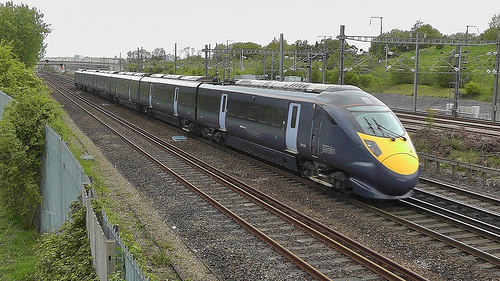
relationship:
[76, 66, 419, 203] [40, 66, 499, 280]
train on tracks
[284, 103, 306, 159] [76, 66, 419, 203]
door on train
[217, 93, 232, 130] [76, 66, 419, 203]
door on train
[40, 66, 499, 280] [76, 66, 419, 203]
tracks for trains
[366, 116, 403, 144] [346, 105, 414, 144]
wipers on windshield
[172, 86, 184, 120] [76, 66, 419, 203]
door on train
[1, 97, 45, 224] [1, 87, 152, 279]
shrub on fence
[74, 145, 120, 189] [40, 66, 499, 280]
grass by tracks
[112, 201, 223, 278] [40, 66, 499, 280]
gravel by tracks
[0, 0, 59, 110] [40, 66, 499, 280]
trees by tracks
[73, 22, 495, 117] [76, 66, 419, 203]
power lines by train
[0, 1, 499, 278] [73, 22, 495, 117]
picture has power lines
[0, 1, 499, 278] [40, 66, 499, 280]
picture has tracks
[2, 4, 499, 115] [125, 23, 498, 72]
background has trees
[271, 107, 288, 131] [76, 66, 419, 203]
window on train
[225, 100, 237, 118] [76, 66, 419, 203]
window on train